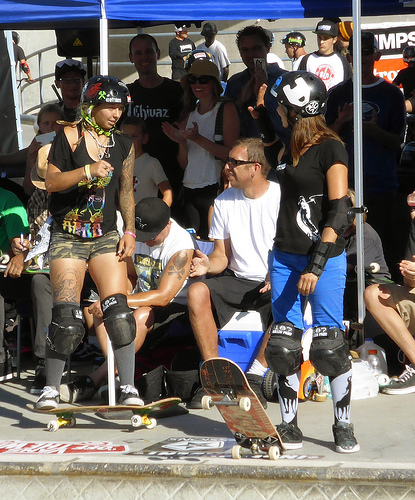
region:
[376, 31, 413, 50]
MPS in white letters.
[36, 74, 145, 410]
A girl skateboarder with knee pads on and army shorts.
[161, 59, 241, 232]
A woman in a brown hat and white shirt clapping.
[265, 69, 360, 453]
A girl skateboarder with blue pants on and a black shirt.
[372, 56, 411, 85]
Orange and white sign behind the people.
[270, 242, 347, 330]
Blue pants on a girl skater.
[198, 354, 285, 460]
An orange and black skateboard with white wheels.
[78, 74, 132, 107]
A black helmet with red and green stickers on it.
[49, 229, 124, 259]
Camo shorts on a skater girl.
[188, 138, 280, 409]
A guy in black sunglasses sitting down with a white shirt on and black shorts.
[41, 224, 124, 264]
camouflage shorts on a woman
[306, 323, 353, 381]
a black kneepad on a woman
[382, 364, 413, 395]
a black and white skate shoe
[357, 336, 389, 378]
a gallon jug with a blue lid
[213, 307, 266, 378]
a blue cooler with a white lid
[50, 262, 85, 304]
a tattoo on a woman's leg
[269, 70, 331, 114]
a black helmet on a woman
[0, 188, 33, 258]
a green shirt on a person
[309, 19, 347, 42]
a black cap on a man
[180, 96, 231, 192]
a white shirt on a woman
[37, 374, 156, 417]
she is on the board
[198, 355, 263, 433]
the board is in the air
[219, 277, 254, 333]
he's sitting on the cooler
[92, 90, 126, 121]
she wearing a helmet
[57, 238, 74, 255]
the shorts are camo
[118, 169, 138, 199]
she has tatoos on her arm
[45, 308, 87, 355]
shes wearing knee pads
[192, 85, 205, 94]
the lady is smiling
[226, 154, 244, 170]
hes wearing sunglasses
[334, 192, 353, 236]
shes wearing elbow pads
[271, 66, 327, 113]
The girl is wearing a helmet.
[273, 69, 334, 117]
The helmet is black.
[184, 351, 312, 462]
The girl is using a skateboard.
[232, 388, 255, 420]
The wheel on the skateboard is white.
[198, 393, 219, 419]
The wheel on the skateboard is white.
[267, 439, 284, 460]
The wheel on the skateboard is white.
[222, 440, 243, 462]
The wheel on the skateboard is white.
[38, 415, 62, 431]
The wheel on the skateboard is white.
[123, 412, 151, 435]
The wheel on the skateboard is white.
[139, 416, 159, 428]
The wheel on the skateboard is white.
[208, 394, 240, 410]
silver metal skateboard axel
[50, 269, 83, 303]
tattoo on leg of woman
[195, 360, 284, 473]
orange and black skateboard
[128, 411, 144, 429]
white hard plastic skateboard wheel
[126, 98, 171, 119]
text on front of shirt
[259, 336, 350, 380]
pair of black knee guards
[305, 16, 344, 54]
man in black and white hat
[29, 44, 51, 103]
shadow of guard rail on wall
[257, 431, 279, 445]
design on bottom of skateboard